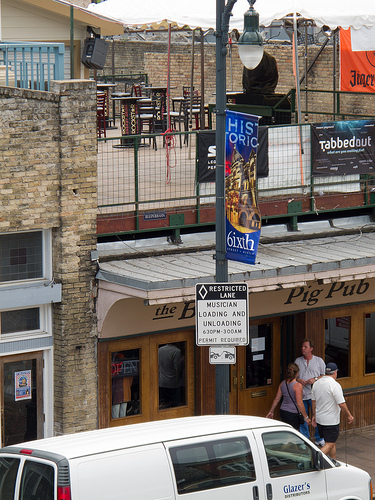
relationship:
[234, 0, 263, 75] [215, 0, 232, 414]
lamp on pole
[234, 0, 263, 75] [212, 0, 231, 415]
lamp on lamp post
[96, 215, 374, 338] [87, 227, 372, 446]
awning on pub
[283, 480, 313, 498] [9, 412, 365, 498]
company name on van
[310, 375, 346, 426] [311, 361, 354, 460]
shirt of man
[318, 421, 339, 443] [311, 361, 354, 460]
shorts of man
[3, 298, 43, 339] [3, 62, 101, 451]
window of a building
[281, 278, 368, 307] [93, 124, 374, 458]
restaurant sign on pub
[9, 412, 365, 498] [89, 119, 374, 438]
van in front of building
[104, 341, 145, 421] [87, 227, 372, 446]
window of pub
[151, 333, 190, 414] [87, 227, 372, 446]
window of pub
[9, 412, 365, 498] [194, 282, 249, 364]
van parked next to a road sign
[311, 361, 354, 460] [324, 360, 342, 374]
man wearing blue hat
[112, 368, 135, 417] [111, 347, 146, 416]
someone standing in a window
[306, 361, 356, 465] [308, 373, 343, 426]
man wearing a shirt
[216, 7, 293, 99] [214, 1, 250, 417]
lamp on a pole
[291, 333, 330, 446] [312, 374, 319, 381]
man wearing watch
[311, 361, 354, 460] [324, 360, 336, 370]
man wearing hat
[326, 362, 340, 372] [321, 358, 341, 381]
blue hat on head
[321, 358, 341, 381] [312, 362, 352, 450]
head of man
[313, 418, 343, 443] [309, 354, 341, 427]
shorts on man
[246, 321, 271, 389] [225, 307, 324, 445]
window on door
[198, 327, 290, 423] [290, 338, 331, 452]
doors next to man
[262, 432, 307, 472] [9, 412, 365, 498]
window of a van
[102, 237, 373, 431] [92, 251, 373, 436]
front of business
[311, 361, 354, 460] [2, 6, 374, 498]
man in photo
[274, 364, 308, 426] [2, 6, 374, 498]
person in photo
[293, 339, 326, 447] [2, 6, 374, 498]
man in photo